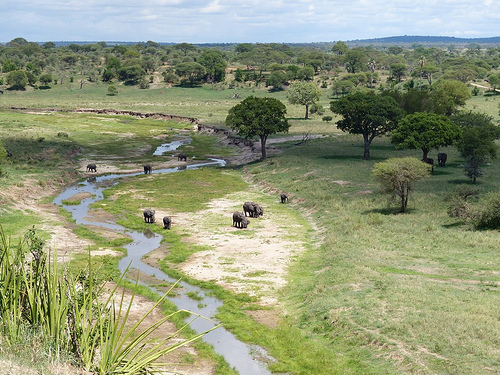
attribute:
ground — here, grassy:
[3, 88, 499, 374]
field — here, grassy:
[3, 88, 499, 373]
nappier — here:
[14, 104, 312, 309]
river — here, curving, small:
[57, 170, 274, 373]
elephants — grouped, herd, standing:
[232, 200, 265, 231]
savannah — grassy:
[2, 31, 499, 374]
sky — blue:
[2, 2, 499, 47]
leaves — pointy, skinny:
[98, 269, 225, 375]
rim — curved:
[1, 165, 78, 221]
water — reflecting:
[55, 173, 107, 207]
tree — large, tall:
[390, 109, 459, 169]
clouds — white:
[66, 3, 499, 35]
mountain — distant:
[349, 34, 499, 46]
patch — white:
[177, 193, 298, 288]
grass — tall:
[341, 193, 388, 230]